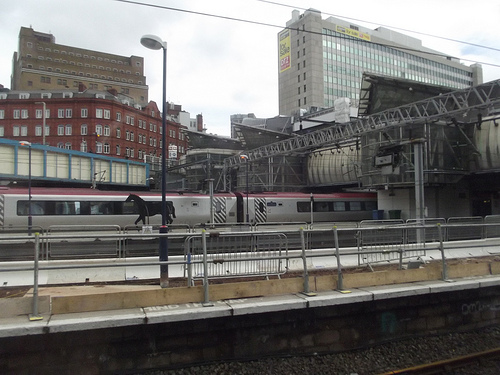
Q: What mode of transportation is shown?
A: Train.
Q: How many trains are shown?
A: 1.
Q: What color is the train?
A: Silver.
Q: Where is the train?
A: On the tracks.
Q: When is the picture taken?
A: Daytime.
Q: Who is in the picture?
A: No one.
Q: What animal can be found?
A: A horse.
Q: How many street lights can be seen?
A: 1.